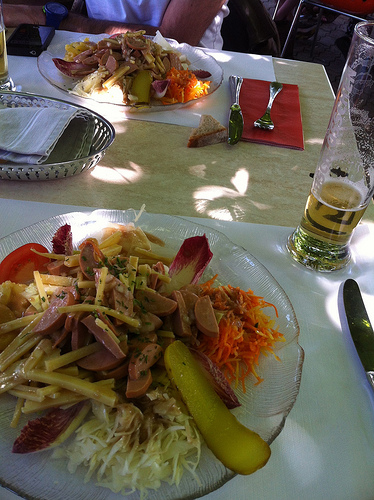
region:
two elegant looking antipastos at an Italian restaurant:
[0, 30, 304, 496]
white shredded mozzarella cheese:
[51, 392, 216, 491]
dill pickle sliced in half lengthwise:
[162, 338, 270, 473]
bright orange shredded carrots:
[197, 272, 279, 379]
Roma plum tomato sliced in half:
[0, 242, 49, 281]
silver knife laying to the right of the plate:
[340, 275, 371, 387]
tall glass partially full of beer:
[283, 24, 371, 275]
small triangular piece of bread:
[187, 111, 226, 146]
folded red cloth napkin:
[234, 76, 303, 147]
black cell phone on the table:
[5, 22, 54, 56]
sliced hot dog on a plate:
[55, 253, 163, 381]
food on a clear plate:
[9, 225, 252, 482]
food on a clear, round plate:
[2, 228, 286, 487]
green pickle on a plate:
[165, 342, 268, 469]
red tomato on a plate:
[0, 241, 44, 277]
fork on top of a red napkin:
[241, 78, 303, 146]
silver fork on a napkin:
[252, 84, 285, 132]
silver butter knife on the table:
[226, 76, 242, 144]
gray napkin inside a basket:
[0, 112, 91, 161]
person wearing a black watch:
[42, 6, 67, 24]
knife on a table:
[226, 61, 250, 150]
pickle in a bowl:
[156, 342, 275, 481]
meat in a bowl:
[84, 310, 161, 388]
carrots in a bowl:
[219, 304, 270, 362]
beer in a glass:
[289, 179, 362, 265]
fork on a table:
[245, 79, 287, 140]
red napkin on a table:
[249, 80, 265, 113]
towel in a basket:
[5, 98, 86, 162]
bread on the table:
[187, 109, 235, 151]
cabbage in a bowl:
[154, 225, 214, 294]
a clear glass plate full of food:
[0, 208, 304, 496]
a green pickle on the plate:
[160, 338, 269, 471]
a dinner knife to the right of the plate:
[338, 274, 369, 383]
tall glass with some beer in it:
[285, 21, 369, 267]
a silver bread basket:
[0, 88, 115, 178]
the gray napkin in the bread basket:
[0, 105, 93, 160]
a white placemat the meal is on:
[0, 200, 369, 492]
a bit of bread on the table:
[187, 110, 225, 144]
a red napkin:
[232, 77, 301, 145]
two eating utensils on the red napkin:
[228, 75, 280, 142]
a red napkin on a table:
[234, 80, 306, 149]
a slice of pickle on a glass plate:
[165, 341, 270, 474]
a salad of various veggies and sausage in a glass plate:
[0, 220, 285, 493]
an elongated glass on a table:
[288, 23, 372, 271]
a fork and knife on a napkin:
[229, 77, 283, 143]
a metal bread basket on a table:
[2, 89, 115, 181]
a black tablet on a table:
[7, 23, 54, 57]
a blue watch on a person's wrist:
[41, 3, 67, 27]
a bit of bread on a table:
[187, 112, 228, 147]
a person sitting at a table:
[6, 1, 229, 49]